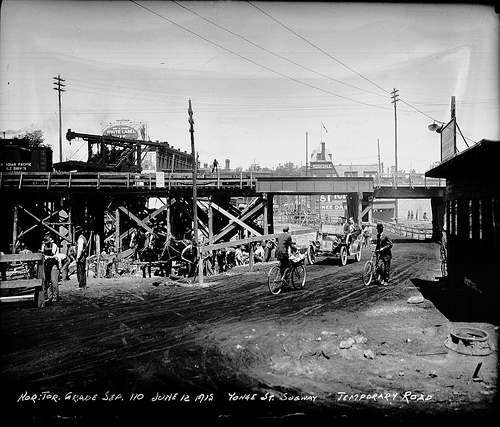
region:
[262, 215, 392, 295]
bicycles in the muddy road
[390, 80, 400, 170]
posts for power lines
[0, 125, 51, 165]
a train starts over the bridge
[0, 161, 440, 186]
bridge built for a train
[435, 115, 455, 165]
billboard mounted over the bridge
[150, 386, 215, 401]
date is June 10, 1913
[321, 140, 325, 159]
chimney on a building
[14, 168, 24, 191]
Small wooden fence post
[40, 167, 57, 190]
Small wooden fence post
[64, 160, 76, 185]
Small wooden fence post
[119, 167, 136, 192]
Small wooden fence post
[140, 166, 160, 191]
Small wooden fence post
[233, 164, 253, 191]
Small wooden fence post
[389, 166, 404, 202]
Small wooden fence post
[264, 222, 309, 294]
man riding a bicycle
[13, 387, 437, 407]
white description of photo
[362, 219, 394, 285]
man holding onto a bicycle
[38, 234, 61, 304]
man wearing a hat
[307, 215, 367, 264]
man riding an old car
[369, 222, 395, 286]
man wearing a hat and suit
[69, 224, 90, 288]
man wearing a hat and vest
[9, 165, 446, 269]
bridge with wood supports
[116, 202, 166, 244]
wood in the shape of an x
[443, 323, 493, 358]
metal object in the dirt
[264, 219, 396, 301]
two men on bicycles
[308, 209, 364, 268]
car on the dirt road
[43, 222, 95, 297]
men standing beside dirt road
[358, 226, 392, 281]
man standing beside his bicycle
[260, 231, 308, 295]
man riding a bicycle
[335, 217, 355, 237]
driver of the car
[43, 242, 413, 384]
tracks on the road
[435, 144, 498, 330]
building on the right side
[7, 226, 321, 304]
railing along the dirt road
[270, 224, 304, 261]
a peson riding a bike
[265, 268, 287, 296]
back tire of the bike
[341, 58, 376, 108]
electrical lines in the sky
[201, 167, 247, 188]
a bridge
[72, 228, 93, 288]
a person standing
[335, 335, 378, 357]
rocks on the ground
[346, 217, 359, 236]
a person sitting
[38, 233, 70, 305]
a man standing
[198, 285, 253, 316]
lines in the dirt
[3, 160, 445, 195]
the over pass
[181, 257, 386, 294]
the bikes on the street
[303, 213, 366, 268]
the car on the road